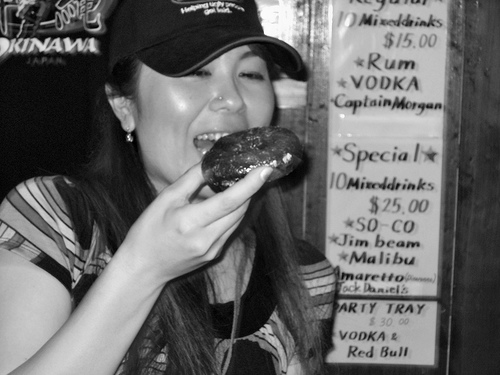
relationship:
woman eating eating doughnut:
[1, 8, 347, 370] [199, 122, 308, 201]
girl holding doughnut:
[0, 0, 336, 374] [201, 121, 303, 197]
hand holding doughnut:
[126, 160, 274, 280] [201, 121, 303, 197]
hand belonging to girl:
[126, 160, 274, 280] [0, 0, 336, 374]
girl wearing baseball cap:
[0, 0, 336, 374] [97, 2, 312, 100]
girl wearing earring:
[0, 0, 336, 374] [124, 130, 136, 143]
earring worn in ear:
[124, 130, 136, 143] [100, 77, 140, 134]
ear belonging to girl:
[100, 77, 140, 134] [0, 0, 336, 374]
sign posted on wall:
[324, 0, 451, 141] [2, 2, 484, 371]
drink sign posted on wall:
[324, 138, 444, 301] [2, 2, 484, 371]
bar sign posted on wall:
[320, 296, 442, 366] [2, 2, 484, 371]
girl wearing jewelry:
[0, 0, 336, 374] [216, 93, 225, 99]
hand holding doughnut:
[116, 160, 273, 283] [204, 125, 305, 194]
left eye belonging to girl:
[180, 66, 219, 84] [0, 0, 336, 374]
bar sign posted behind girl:
[306, 2, 470, 368] [0, 0, 336, 374]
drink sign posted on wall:
[287, 2, 465, 363] [2, 2, 484, 371]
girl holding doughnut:
[0, 0, 336, 374] [199, 123, 311, 195]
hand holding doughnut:
[126, 160, 274, 280] [199, 123, 311, 195]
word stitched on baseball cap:
[202, 7, 217, 17] [97, 2, 309, 84]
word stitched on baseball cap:
[216, 5, 231, 14] [97, 2, 309, 84]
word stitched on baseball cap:
[179, 1, 209, 14] [97, 2, 309, 84]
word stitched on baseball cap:
[207, 0, 226, 8] [97, 2, 309, 84]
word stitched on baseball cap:
[224, 0, 246, 13] [97, 2, 309, 84]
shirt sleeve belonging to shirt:
[1, 173, 81, 293] [2, 170, 338, 373]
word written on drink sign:
[340, 140, 422, 175] [324, 138, 444, 301]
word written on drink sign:
[347, 174, 387, 191] [324, 138, 444, 301]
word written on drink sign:
[373, 231, 420, 249] [324, 138, 444, 301]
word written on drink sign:
[348, 249, 417, 266] [324, 138, 444, 301]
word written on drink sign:
[333, 264, 403, 281] [324, 138, 444, 301]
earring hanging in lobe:
[124, 130, 136, 143] [120, 114, 136, 132]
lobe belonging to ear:
[120, 114, 136, 132] [102, 81, 139, 131]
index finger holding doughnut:
[194, 167, 288, 217] [199, 123, 311, 195]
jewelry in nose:
[211, 92, 225, 102] [208, 69, 250, 117]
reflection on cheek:
[149, 80, 189, 122] [142, 75, 202, 143]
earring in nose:
[124, 124, 143, 144] [206, 69, 247, 119]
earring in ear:
[124, 124, 143, 144] [101, 78, 140, 144]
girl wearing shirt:
[1, 0, 327, 370] [0, 170, 338, 374]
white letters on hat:
[175, 2, 255, 20] [97, 0, 314, 88]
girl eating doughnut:
[1, 0, 327, 370] [187, 120, 310, 201]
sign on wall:
[304, 0, 478, 372] [304, 8, 483, 164]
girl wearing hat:
[0, 0, 336, 374] [78, 0, 328, 100]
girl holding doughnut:
[0, 0, 336, 374] [191, 124, 310, 191]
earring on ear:
[124, 124, 143, 144] [102, 81, 142, 134]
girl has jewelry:
[0, 0, 336, 374] [216, 93, 225, 99]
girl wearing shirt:
[0, 0, 336, 374] [2, 174, 358, 366]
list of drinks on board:
[308, 1, 467, 362] [296, 5, 461, 370]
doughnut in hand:
[187, 120, 310, 201] [147, 150, 274, 269]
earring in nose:
[124, 130, 136, 143] [214, 65, 247, 115]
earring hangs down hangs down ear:
[117, 125, 136, 143] [95, 84, 154, 153]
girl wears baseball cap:
[0, 0, 336, 374] [97, 2, 309, 84]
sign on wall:
[304, 0, 478, 372] [313, 13, 467, 358]